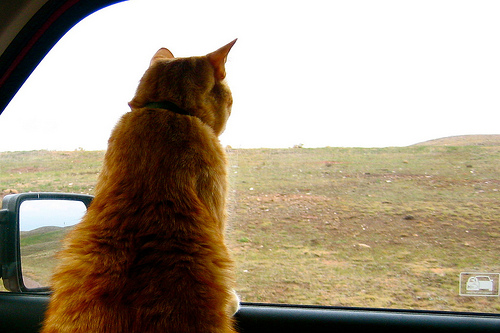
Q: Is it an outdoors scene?
A: Yes, it is outdoors.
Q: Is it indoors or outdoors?
A: It is outdoors.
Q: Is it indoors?
A: No, it is outdoors.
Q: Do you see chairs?
A: No, there are no chairs.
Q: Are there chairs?
A: No, there are no chairs.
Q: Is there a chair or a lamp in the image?
A: No, there are no chairs or lamps.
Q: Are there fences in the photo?
A: No, there are no fences.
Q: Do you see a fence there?
A: No, there are no fences.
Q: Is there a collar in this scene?
A: Yes, there is a collar.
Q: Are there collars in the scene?
A: Yes, there is a collar.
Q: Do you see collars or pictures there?
A: Yes, there is a collar.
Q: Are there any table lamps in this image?
A: No, there are no table lamps.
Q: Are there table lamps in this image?
A: No, there are no table lamps.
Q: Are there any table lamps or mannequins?
A: No, there are no table lamps or mannequins.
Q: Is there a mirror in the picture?
A: Yes, there is a mirror.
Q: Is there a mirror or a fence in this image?
A: Yes, there is a mirror.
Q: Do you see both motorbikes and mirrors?
A: No, there is a mirror but no motorcycles.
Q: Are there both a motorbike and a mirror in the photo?
A: No, there is a mirror but no motorcycles.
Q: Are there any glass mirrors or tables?
A: Yes, there is a glass mirror.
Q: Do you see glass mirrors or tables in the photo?
A: Yes, there is a glass mirror.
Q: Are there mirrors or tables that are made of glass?
A: Yes, the mirror is made of glass.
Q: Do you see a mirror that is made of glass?
A: Yes, there is a mirror that is made of glass.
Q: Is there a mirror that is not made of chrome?
A: Yes, there is a mirror that is made of glass.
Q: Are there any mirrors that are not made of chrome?
A: Yes, there is a mirror that is made of glass.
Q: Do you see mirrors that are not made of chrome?
A: Yes, there is a mirror that is made of glass.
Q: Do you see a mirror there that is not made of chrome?
A: Yes, there is a mirror that is made of glass.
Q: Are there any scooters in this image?
A: No, there are no scooters.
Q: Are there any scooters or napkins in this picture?
A: No, there are no scooters or napkins.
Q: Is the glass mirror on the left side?
A: Yes, the mirror is on the left of the image.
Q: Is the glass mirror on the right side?
A: No, the mirror is on the left of the image.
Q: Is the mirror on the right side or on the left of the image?
A: The mirror is on the left of the image.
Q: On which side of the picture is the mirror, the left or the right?
A: The mirror is on the left of the image.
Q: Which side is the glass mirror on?
A: The mirror is on the left of the image.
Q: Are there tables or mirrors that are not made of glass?
A: No, there is a mirror but it is made of glass.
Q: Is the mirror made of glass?
A: Yes, the mirror is made of glass.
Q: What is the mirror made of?
A: The mirror is made of glass.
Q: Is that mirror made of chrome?
A: No, the mirror is made of glass.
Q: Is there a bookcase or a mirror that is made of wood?
A: No, there is a mirror but it is made of glass.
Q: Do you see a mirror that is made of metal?
A: No, there is a mirror but it is made of glass.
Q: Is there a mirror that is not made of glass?
A: No, there is a mirror but it is made of glass.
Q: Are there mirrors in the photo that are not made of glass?
A: No, there is a mirror but it is made of glass.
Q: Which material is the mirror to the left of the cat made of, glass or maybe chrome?
A: The mirror is made of glass.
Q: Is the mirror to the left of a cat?
A: Yes, the mirror is to the left of a cat.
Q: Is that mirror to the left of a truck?
A: No, the mirror is to the left of a cat.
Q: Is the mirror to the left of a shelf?
A: No, the mirror is to the left of a cat.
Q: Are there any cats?
A: Yes, there is a cat.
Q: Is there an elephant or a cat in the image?
A: Yes, there is a cat.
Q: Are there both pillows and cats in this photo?
A: No, there is a cat but no pillows.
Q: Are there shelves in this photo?
A: No, there are no shelves.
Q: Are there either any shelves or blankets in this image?
A: No, there are no shelves or blankets.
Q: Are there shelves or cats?
A: Yes, there is a cat.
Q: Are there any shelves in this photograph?
A: No, there are no shelves.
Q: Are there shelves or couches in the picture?
A: No, there are no shelves or couches.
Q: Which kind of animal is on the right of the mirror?
A: The animal is a cat.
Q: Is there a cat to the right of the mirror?
A: Yes, there is a cat to the right of the mirror.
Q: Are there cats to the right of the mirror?
A: Yes, there is a cat to the right of the mirror.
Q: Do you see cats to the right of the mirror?
A: Yes, there is a cat to the right of the mirror.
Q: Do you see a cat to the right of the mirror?
A: Yes, there is a cat to the right of the mirror.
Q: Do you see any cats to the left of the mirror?
A: No, the cat is to the right of the mirror.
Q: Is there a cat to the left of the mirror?
A: No, the cat is to the right of the mirror.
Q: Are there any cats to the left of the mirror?
A: No, the cat is to the right of the mirror.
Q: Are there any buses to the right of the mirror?
A: No, there is a cat to the right of the mirror.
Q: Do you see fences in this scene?
A: No, there are no fences.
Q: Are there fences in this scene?
A: No, there are no fences.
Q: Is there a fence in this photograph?
A: No, there are no fences.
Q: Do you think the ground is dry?
A: Yes, the ground is dry.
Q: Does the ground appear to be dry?
A: Yes, the ground is dry.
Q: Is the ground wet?
A: No, the ground is dry.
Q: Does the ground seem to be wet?
A: No, the ground is dry.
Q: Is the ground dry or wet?
A: The ground is dry.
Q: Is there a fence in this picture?
A: No, there are no fences.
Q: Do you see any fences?
A: No, there are no fences.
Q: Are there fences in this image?
A: No, there are no fences.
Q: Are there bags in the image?
A: No, there are no bags.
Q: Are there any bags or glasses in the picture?
A: No, there are no bags or glasses.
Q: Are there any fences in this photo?
A: No, there are no fences.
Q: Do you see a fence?
A: No, there are no fences.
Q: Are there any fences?
A: No, there are no fences.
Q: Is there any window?
A: Yes, there is a window.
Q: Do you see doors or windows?
A: Yes, there is a window.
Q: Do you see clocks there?
A: No, there are no clocks.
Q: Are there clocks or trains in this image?
A: No, there are no clocks or trains.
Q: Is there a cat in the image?
A: Yes, there is a cat.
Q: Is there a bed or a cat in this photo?
A: Yes, there is a cat.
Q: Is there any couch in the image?
A: No, there are no couches.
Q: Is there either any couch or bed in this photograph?
A: No, there are no couches or beds.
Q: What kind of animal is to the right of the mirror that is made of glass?
A: The animal is a cat.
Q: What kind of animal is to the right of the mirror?
A: The animal is a cat.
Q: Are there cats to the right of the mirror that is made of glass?
A: Yes, there is a cat to the right of the mirror.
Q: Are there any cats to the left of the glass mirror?
A: No, the cat is to the right of the mirror.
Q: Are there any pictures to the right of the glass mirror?
A: No, there is a cat to the right of the mirror.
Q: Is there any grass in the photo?
A: Yes, there is grass.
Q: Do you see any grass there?
A: Yes, there is grass.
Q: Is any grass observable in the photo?
A: Yes, there is grass.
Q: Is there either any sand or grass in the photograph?
A: Yes, there is grass.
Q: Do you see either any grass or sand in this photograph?
A: Yes, there is grass.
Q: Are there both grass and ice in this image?
A: No, there is grass but no ice.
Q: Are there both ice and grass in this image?
A: No, there is grass but no ice.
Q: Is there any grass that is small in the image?
A: Yes, there is small grass.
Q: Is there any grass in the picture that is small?
A: Yes, there is grass that is small.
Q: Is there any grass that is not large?
A: Yes, there is small grass.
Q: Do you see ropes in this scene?
A: No, there are no ropes.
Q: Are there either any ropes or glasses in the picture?
A: No, there are no ropes or glasses.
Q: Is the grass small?
A: Yes, the grass is small.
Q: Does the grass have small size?
A: Yes, the grass is small.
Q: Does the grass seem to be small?
A: Yes, the grass is small.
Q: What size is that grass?
A: The grass is small.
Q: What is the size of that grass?
A: The grass is small.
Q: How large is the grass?
A: The grass is small.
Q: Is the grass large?
A: No, the grass is small.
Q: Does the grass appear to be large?
A: No, the grass is small.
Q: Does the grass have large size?
A: No, the grass is small.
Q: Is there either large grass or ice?
A: No, there is grass but it is small.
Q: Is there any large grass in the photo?
A: No, there is grass but it is small.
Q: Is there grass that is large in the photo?
A: No, there is grass but it is small.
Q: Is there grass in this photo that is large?
A: No, there is grass but it is small.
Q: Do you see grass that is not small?
A: No, there is grass but it is small.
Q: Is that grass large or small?
A: The grass is small.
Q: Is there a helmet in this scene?
A: No, there are no helmets.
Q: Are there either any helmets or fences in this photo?
A: No, there are no helmets or fences.